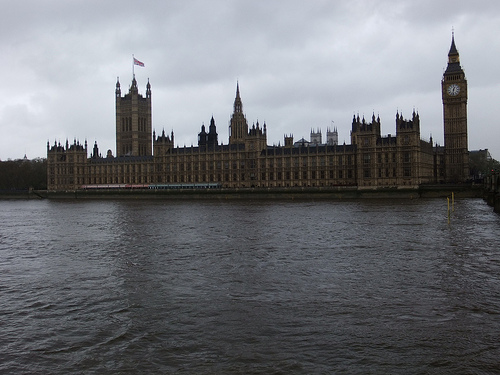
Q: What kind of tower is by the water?
A: Clock tower.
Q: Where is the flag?
A: On top of the building.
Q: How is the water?
A: Calm and dark.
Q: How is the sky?
A: Gray and cloudy.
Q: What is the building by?
A: The water.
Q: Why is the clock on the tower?
A: To tell time.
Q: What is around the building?
A: Grass.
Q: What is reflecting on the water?
A: Light.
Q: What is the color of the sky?
A: Grey.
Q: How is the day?
A: Cloudy.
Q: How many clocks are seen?
A: 1.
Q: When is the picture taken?
A: Daytime.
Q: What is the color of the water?
A: Blue.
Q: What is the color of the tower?
A: Brown.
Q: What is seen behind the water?
A: Palace.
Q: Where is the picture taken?
A: In London, England.